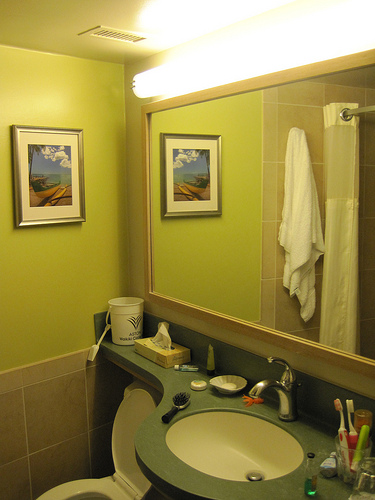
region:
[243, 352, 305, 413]
a gray sink faucet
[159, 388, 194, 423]
a black brush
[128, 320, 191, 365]
a small box of tissue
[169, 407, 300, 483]
a white sink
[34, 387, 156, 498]
part of a white toilet seat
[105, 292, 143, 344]
a large white cup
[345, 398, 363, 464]
part of a toothbrush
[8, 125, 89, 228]
a gray wall picture frame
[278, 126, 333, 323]
a large white towel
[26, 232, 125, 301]
part of a green wall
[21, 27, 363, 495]
this is a bathroom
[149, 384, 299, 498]
this is a sink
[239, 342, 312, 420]
this is a faucet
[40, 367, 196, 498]
this is a toilet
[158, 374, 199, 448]
a hair brush on counter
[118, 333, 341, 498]
counter top is green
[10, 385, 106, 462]
brown tile on wall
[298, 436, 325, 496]
small bottle on counter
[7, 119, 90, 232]
picture hanging on the wall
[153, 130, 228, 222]
reflection of a picture hanging on the wall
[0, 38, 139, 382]
puke green colored wall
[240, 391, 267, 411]
orange toy gold fish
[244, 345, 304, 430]
shiny silver metal faucet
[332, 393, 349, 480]
red and white tooth brush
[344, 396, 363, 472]
red and white tooth brush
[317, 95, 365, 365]
white vinyl shower curtain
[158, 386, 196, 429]
black and silver plastic hair brush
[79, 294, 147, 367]
white plastic bucket and shovel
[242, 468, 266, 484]
drain in a sink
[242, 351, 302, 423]
faucet near a sink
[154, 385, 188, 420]
brush on a bathroom counter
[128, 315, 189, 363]
tissues on a bathroom counter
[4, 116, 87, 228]
picture on a wall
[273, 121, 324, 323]
towel hanging in a shower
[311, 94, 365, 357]
shower curtain on a rod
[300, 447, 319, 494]
bottle on a bathroom counter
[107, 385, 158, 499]
lid on a toilet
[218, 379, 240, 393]
soap in a dish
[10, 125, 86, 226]
framed print on bathroom wall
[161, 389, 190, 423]
black and silver plastic hairbrush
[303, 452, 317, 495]
small vial of mouthwash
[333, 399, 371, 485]
toothbrushes in drinking glass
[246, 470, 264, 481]
chrome bathroom sink drain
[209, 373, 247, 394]
fluted soap dish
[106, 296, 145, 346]
plastic hotel ice bucket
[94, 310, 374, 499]
green formica hotel bathroom counter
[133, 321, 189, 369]
opened box of tissues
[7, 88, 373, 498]
hotel bathroom decorated in olive green, avocado green and gold